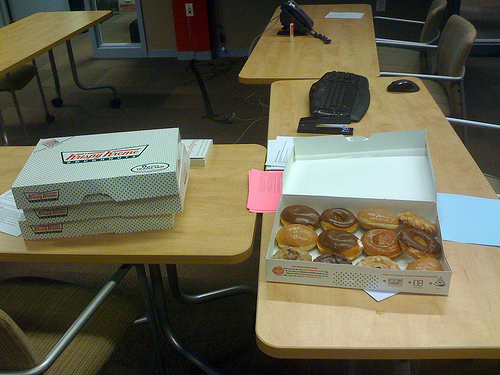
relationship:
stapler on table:
[296, 115, 354, 138] [255, 76, 498, 360]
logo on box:
[63, 143, 150, 163] [10, 155, 191, 240]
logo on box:
[25, 188, 60, 205] [24, 147, 191, 224]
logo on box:
[30, 223, 65, 236] [10, 155, 191, 240]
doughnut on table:
[280, 205, 322, 230] [255, 76, 498, 360]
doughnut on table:
[280, 205, 422, 259] [255, 76, 498, 360]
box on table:
[10, 155, 191, 240] [3, 143, 267, 266]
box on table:
[24, 147, 191, 224] [3, 143, 267, 266]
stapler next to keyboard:
[296, 115, 354, 138] [309, 71, 370, 121]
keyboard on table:
[309, 71, 370, 121] [255, 76, 498, 360]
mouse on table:
[386, 80, 420, 93] [255, 76, 498, 360]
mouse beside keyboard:
[386, 80, 420, 93] [309, 71, 370, 121]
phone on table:
[279, 1, 314, 36] [239, 4, 380, 79]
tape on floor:
[188, 58, 233, 127] [3, 20, 496, 372]